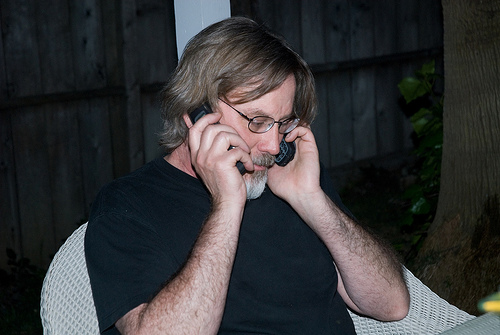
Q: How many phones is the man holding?
A: Two.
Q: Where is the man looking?
A: Down.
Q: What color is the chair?
A: White.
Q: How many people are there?
A: One.